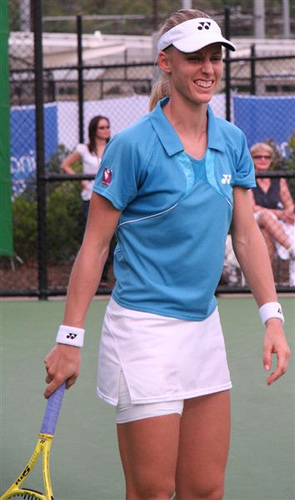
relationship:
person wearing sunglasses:
[56, 116, 112, 285] [95, 123, 110, 134]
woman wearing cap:
[41, 7, 292, 498] [157, 17, 235, 57]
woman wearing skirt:
[41, 7, 292, 498] [96, 301, 233, 408]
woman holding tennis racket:
[41, 7, 292, 498] [1, 379, 65, 498]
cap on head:
[157, 17, 235, 57] [150, 2, 223, 104]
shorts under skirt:
[115, 379, 184, 424] [96, 301, 233, 408]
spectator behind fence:
[248, 137, 293, 284] [4, 0, 293, 291]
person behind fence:
[60, 116, 112, 285] [4, 0, 293, 291]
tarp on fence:
[1, 2, 15, 271] [4, 0, 293, 291]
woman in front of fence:
[41, 7, 292, 498] [4, 0, 293, 291]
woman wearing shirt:
[41, 7, 292, 498] [89, 93, 258, 322]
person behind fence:
[56, 116, 112, 285] [4, 0, 293, 291]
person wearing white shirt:
[60, 116, 112, 285] [74, 142, 106, 201]